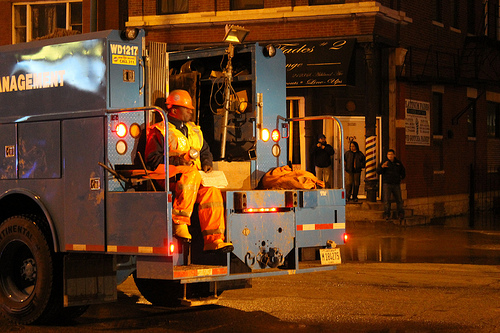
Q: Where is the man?
A: On the vehicle.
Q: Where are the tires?
A: On the car.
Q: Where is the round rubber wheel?
A: On the road.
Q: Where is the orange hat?
A: On the man riding in the back of the truck.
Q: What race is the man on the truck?
A: African American.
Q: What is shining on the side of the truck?
A: Reflection.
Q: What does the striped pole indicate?
A: Barber shop.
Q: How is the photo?
A: Clear.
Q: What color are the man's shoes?
A: Yellow.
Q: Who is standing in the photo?
A: Three people.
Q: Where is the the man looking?
A: Sideways.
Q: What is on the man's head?
A: A helmet.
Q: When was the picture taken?
A: At night.